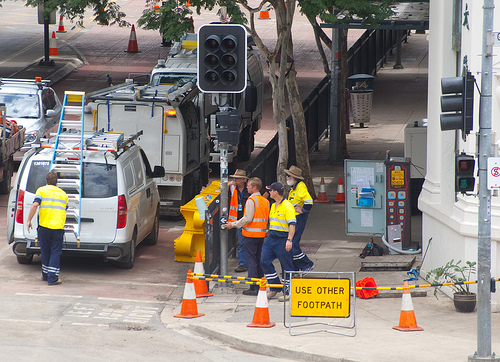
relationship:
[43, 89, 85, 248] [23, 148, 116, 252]
blue/yellow ladder on truck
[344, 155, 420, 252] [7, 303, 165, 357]
box on street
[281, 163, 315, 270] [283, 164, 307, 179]
guy wearing hat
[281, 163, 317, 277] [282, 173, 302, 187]
guy with beard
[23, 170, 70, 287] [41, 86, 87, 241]
guy holding ladder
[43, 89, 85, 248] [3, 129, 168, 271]
blue/yellow ladder on truck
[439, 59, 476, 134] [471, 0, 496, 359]
traffic light attached to pole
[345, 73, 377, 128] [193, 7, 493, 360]
can on sidewalk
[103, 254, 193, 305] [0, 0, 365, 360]
part of a road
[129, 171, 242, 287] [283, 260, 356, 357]
part of a banner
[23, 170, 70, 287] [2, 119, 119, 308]
guy loading ladder on van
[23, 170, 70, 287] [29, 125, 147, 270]
guy reaching towards ladder on back of van